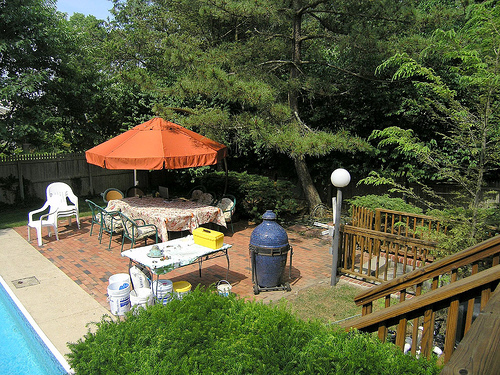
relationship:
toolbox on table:
[186, 227, 223, 250] [118, 227, 233, 299]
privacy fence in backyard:
[0, 150, 150, 205] [24, 148, 475, 358]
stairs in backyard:
[336, 231, 498, 369] [13, 154, 378, 370]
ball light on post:
[327, 164, 354, 194] [329, 187, 346, 287]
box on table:
[190, 225, 225, 251] [135, 237, 268, 279]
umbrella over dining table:
[86, 116, 228, 170] [95, 190, 229, 243]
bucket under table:
[106, 279, 133, 317] [116, 232, 236, 297]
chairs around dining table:
[84, 191, 172, 251] [101, 189, 227, 239]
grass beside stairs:
[288, 279, 369, 323] [358, 227, 498, 364]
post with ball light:
[330, 190, 346, 285] [328, 166, 353, 190]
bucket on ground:
[105, 279, 134, 317] [2, 192, 434, 373]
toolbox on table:
[191, 226, 225, 250] [116, 229, 232, 291]